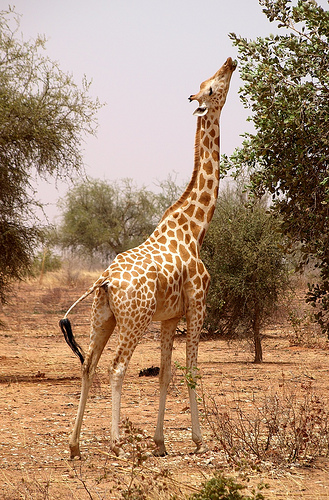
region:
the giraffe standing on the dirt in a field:
[57, 55, 237, 454]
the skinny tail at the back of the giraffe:
[56, 275, 103, 359]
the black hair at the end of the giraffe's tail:
[58, 317, 102, 393]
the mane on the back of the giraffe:
[159, 104, 204, 227]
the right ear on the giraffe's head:
[192, 104, 207, 115]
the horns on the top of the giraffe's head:
[188, 94, 197, 101]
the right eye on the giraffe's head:
[207, 86, 212, 95]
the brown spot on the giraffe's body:
[178, 244, 189, 260]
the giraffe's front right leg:
[186, 284, 206, 452]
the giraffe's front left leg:
[153, 318, 176, 455]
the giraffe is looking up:
[167, 46, 256, 239]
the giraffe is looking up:
[190, 55, 263, 177]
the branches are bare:
[190, 382, 289, 476]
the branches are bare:
[65, 456, 108, 498]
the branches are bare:
[202, 396, 244, 461]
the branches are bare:
[236, 413, 301, 490]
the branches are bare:
[232, 367, 324, 459]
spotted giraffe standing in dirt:
[24, 46, 258, 451]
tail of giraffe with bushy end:
[47, 280, 115, 381]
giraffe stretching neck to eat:
[185, 37, 256, 183]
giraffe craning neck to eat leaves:
[180, 32, 311, 157]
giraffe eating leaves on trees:
[181, 11, 307, 213]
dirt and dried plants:
[86, 369, 302, 485]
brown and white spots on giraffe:
[131, 239, 187, 301]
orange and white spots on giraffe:
[144, 237, 201, 319]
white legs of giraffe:
[46, 375, 213, 459]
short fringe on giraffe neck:
[162, 112, 220, 248]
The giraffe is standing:
[61, 54, 244, 460]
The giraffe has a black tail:
[54, 314, 88, 369]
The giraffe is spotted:
[65, 53, 241, 459]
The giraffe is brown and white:
[63, 53, 239, 463]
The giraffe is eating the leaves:
[58, 48, 237, 459]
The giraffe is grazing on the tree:
[58, 56, 238, 459]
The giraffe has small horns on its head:
[183, 90, 203, 105]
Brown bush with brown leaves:
[200, 372, 325, 468]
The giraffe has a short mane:
[158, 106, 204, 228]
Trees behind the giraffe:
[1, 71, 275, 360]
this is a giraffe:
[58, 53, 243, 463]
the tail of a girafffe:
[50, 274, 108, 359]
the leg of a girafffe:
[62, 288, 119, 465]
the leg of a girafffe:
[103, 282, 153, 457]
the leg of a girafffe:
[150, 310, 178, 458]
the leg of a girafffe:
[181, 286, 217, 457]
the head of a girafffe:
[188, 52, 241, 116]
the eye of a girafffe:
[203, 83, 214, 96]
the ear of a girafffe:
[190, 102, 207, 117]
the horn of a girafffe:
[184, 88, 201, 101]